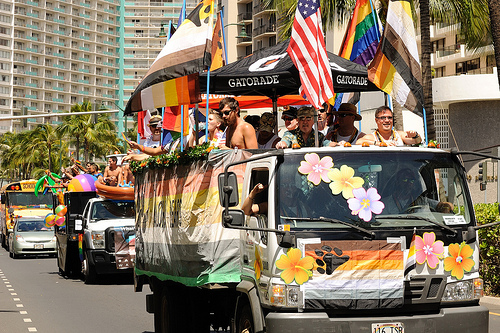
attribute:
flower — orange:
[276, 241, 314, 290]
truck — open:
[132, 138, 472, 331]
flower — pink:
[413, 234, 446, 274]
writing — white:
[225, 76, 283, 89]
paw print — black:
[311, 241, 352, 278]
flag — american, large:
[287, 1, 336, 118]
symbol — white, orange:
[251, 51, 290, 72]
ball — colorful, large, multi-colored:
[68, 172, 99, 192]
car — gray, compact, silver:
[11, 216, 59, 256]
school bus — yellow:
[4, 178, 58, 236]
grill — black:
[269, 282, 487, 329]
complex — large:
[4, 0, 167, 141]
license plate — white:
[369, 321, 396, 331]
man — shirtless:
[214, 94, 255, 159]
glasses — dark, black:
[220, 108, 235, 118]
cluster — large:
[2, 104, 121, 160]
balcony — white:
[440, 66, 500, 112]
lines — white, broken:
[0, 263, 44, 328]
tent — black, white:
[207, 39, 377, 133]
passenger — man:
[255, 168, 319, 219]